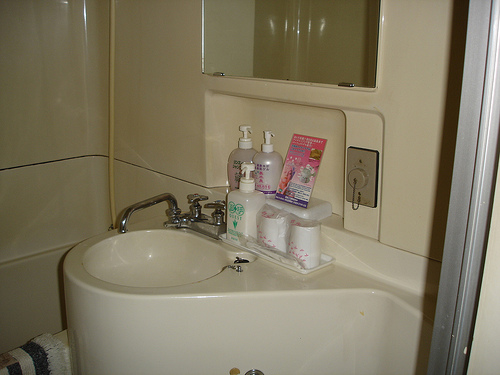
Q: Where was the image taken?
A: It was taken at the bathroom.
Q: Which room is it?
A: It is a bathroom.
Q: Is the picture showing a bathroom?
A: Yes, it is showing a bathroom.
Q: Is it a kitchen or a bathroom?
A: It is a bathroom.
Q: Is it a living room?
A: No, it is a bathroom.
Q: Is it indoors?
A: Yes, it is indoors.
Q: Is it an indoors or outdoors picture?
A: It is indoors.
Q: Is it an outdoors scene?
A: No, it is indoors.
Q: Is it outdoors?
A: No, it is indoors.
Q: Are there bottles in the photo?
A: Yes, there is a bottle.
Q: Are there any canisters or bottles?
A: Yes, there is a bottle.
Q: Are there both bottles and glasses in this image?
A: No, there is a bottle but no glasses.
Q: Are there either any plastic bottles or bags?
A: Yes, there is a plastic bottle.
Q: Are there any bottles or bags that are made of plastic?
A: Yes, the bottle is made of plastic.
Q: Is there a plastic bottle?
A: Yes, there is a bottle that is made of plastic.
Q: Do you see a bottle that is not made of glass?
A: Yes, there is a bottle that is made of plastic.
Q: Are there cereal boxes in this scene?
A: No, there are no cereal boxes.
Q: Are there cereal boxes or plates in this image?
A: No, there are no cereal boxes or plates.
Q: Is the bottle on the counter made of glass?
A: No, the bottle is made of plastic.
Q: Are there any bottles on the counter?
A: Yes, there is a bottle on the counter.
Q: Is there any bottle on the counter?
A: Yes, there is a bottle on the counter.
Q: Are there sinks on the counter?
A: No, there is a bottle on the counter.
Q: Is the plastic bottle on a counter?
A: Yes, the bottle is on a counter.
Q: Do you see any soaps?
A: Yes, there is a soap.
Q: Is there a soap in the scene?
A: Yes, there is a soap.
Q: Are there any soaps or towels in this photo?
A: Yes, there is a soap.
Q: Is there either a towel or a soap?
A: Yes, there is a soap.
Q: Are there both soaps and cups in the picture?
A: Yes, there are both a soap and a cup.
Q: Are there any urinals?
A: No, there are no urinals.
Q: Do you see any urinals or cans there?
A: No, there are no urinals or cans.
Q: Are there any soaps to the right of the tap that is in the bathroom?
A: Yes, there is a soap to the right of the tap.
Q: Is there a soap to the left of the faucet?
A: No, the soap is to the right of the faucet.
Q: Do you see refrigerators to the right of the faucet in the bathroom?
A: No, there is a soap to the right of the faucet.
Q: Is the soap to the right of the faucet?
A: Yes, the soap is to the right of the faucet.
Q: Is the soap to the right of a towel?
A: No, the soap is to the right of the faucet.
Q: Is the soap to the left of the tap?
A: No, the soap is to the right of the tap.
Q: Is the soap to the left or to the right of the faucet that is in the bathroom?
A: The soap is to the right of the faucet.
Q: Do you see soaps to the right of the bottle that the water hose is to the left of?
A: Yes, there is a soap to the right of the bottle.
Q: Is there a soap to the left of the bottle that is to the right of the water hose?
A: No, the soap is to the right of the bottle.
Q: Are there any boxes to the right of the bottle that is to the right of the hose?
A: No, there is a soap to the right of the bottle.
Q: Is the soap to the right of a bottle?
A: Yes, the soap is to the right of a bottle.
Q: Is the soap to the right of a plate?
A: No, the soap is to the right of a bottle.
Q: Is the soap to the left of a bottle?
A: No, the soap is to the right of a bottle.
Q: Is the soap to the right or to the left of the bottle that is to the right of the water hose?
A: The soap is to the right of the bottle.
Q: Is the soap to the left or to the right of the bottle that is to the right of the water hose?
A: The soap is to the right of the bottle.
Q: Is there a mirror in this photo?
A: Yes, there is a mirror.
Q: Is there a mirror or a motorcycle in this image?
A: Yes, there is a mirror.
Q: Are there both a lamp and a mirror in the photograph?
A: No, there is a mirror but no lamps.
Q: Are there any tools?
A: No, there are no tools.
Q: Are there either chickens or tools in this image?
A: No, there are no tools or chickens.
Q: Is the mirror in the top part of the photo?
A: Yes, the mirror is in the top of the image.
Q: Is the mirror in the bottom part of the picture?
A: No, the mirror is in the top of the image.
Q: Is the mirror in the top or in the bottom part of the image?
A: The mirror is in the top of the image.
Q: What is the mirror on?
A: The mirror is on the wall.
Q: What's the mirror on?
A: The mirror is on the wall.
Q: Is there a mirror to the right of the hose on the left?
A: Yes, there is a mirror to the right of the hose.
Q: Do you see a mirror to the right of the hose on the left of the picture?
A: Yes, there is a mirror to the right of the hose.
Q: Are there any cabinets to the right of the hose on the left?
A: No, there is a mirror to the right of the hose.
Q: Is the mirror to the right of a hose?
A: Yes, the mirror is to the right of a hose.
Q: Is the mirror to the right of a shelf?
A: No, the mirror is to the right of a hose.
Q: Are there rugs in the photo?
A: No, there are no rugs.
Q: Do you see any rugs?
A: No, there are no rugs.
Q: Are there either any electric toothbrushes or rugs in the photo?
A: No, there are no rugs or electric toothbrushes.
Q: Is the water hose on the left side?
A: Yes, the water hose is on the left of the image.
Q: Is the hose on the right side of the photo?
A: No, the hose is on the left of the image.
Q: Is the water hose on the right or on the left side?
A: The water hose is on the left of the image.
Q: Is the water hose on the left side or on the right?
A: The water hose is on the left of the image.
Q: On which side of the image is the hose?
A: The hose is on the left of the image.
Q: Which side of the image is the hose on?
A: The hose is on the left of the image.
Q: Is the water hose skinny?
A: Yes, the water hose is skinny.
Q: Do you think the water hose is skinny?
A: Yes, the water hose is skinny.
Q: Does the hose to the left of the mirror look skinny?
A: Yes, the water hose is skinny.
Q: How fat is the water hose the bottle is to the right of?
A: The hose is skinny.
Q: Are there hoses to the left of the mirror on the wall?
A: Yes, there is a hose to the left of the mirror.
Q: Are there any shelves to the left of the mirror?
A: No, there is a hose to the left of the mirror.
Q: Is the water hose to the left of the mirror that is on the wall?
A: Yes, the water hose is to the left of the mirror.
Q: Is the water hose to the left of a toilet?
A: No, the water hose is to the left of the mirror.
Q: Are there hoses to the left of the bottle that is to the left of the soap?
A: Yes, there is a hose to the left of the bottle.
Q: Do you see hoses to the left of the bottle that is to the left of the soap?
A: Yes, there is a hose to the left of the bottle.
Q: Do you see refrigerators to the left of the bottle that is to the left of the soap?
A: No, there is a hose to the left of the bottle.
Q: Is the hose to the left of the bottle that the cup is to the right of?
A: Yes, the hose is to the left of the bottle.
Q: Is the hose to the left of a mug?
A: No, the hose is to the left of the bottle.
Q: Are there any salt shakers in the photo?
A: No, there are no salt shakers.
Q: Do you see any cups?
A: Yes, there is a cup.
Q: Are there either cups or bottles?
A: Yes, there is a cup.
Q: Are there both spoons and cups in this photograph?
A: No, there is a cup but no spoons.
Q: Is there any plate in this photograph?
A: No, there are no plates.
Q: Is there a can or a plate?
A: No, there are no plates or cans.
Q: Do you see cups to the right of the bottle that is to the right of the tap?
A: Yes, there is a cup to the right of the bottle.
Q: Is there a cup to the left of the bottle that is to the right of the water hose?
A: No, the cup is to the right of the bottle.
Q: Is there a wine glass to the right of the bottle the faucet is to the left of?
A: No, there is a cup to the right of the bottle.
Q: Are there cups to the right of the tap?
A: Yes, there is a cup to the right of the tap.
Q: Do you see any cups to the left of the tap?
A: No, the cup is to the right of the tap.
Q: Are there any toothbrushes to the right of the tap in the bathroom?
A: No, there is a cup to the right of the faucet.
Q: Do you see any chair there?
A: No, there are no chairs.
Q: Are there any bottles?
A: Yes, there is a bottle.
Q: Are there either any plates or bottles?
A: Yes, there is a bottle.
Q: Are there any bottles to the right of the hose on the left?
A: Yes, there is a bottle to the right of the water hose.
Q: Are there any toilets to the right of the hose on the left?
A: No, there is a bottle to the right of the hose.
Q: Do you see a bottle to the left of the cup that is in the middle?
A: Yes, there is a bottle to the left of the cup.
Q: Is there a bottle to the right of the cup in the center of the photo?
A: No, the bottle is to the left of the cup.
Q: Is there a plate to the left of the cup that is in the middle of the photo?
A: No, there is a bottle to the left of the cup.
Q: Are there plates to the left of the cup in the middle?
A: No, there is a bottle to the left of the cup.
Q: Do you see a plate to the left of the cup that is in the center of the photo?
A: No, there is a bottle to the left of the cup.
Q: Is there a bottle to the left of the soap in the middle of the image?
A: Yes, there is a bottle to the left of the soap.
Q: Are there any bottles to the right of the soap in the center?
A: No, the bottle is to the left of the soap.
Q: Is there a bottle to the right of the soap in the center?
A: No, the bottle is to the left of the soap.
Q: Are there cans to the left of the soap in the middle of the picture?
A: No, there is a bottle to the left of the soap.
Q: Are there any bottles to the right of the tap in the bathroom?
A: Yes, there is a bottle to the right of the tap.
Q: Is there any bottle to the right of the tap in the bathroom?
A: Yes, there is a bottle to the right of the tap.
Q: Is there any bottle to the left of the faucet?
A: No, the bottle is to the right of the faucet.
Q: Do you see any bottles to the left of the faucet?
A: No, the bottle is to the right of the faucet.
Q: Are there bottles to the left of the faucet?
A: No, the bottle is to the right of the faucet.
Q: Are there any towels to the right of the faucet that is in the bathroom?
A: No, there is a bottle to the right of the faucet.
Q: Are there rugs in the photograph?
A: No, there are no rugs.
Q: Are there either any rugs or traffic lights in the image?
A: No, there are no rugs or traffic lights.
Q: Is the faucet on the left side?
A: Yes, the faucet is on the left of the image.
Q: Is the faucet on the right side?
A: No, the faucet is on the left of the image.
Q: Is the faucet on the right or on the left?
A: The faucet is on the left of the image.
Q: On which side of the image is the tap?
A: The tap is on the left of the image.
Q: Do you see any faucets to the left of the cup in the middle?
A: Yes, there is a faucet to the left of the cup.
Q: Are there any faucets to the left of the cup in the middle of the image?
A: Yes, there is a faucet to the left of the cup.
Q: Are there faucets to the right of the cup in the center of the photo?
A: No, the faucet is to the left of the cup.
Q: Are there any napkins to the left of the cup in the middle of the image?
A: No, there is a faucet to the left of the cup.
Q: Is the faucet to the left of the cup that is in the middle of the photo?
A: Yes, the faucet is to the left of the cup.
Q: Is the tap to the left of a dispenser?
A: No, the tap is to the left of the cup.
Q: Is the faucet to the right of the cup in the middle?
A: No, the faucet is to the left of the cup.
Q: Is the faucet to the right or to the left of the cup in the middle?
A: The faucet is to the left of the cup.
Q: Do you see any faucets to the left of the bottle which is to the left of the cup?
A: Yes, there is a faucet to the left of the bottle.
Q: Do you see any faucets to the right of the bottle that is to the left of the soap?
A: No, the faucet is to the left of the bottle.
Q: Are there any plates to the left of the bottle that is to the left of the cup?
A: No, there is a faucet to the left of the bottle.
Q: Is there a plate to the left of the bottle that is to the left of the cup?
A: No, there is a faucet to the left of the bottle.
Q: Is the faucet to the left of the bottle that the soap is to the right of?
A: Yes, the faucet is to the left of the bottle.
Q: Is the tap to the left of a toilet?
A: No, the tap is to the left of the bottle.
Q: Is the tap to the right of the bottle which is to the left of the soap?
A: No, the tap is to the left of the bottle.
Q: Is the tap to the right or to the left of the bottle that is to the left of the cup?
A: The tap is to the left of the bottle.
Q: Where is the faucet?
A: The faucet is in the bathroom.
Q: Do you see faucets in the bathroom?
A: Yes, there is a faucet in the bathroom.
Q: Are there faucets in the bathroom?
A: Yes, there is a faucet in the bathroom.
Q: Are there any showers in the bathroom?
A: No, there is a faucet in the bathroom.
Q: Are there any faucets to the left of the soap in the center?
A: Yes, there is a faucet to the left of the soap.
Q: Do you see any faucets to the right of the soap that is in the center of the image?
A: No, the faucet is to the left of the soap.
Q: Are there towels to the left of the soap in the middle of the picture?
A: No, there is a faucet to the left of the soap.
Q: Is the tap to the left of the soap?
A: Yes, the tap is to the left of the soap.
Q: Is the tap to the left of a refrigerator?
A: No, the tap is to the left of the soap.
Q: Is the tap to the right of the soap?
A: No, the tap is to the left of the soap.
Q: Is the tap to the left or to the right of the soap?
A: The tap is to the left of the soap.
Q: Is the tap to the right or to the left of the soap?
A: The tap is to the left of the soap.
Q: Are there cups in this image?
A: Yes, there is a cup.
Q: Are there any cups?
A: Yes, there is a cup.